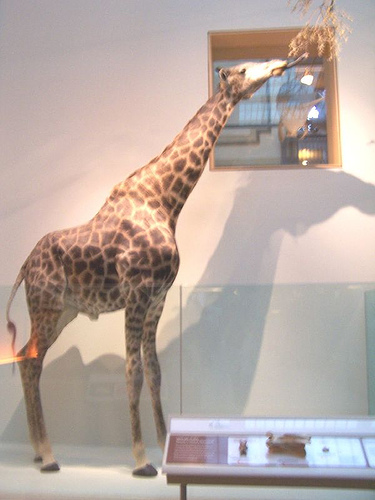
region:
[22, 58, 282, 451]
giraffe is eating leaves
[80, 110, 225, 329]
brown and orange spots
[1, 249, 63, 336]
giraffe has thin tail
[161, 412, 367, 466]
information on stand in front of giraffe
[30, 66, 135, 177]
white wall behind giraffe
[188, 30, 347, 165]
small window near giraffe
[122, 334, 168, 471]
giraffe has light brown legs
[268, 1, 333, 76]
small branch near window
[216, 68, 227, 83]
giraffe has small horns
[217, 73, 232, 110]
giraffe has dark ears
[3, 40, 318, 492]
Tall brown and tan giraffe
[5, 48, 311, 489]
This is not a real giraffe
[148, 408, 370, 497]
Small information sign infront of display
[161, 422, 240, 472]
White lettering on brown information sign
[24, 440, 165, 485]
Black hooves of giraffe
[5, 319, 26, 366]
Small piece of brown hair on giraffe tail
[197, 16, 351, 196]
Small brown window on white wall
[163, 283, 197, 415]
Black line going down wall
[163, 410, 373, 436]
White heading on information board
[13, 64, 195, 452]
Brown spots on giraffe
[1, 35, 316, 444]
the display of the giraffe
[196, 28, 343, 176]
the window in the wall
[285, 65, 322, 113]
the reflection on the window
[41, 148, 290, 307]
the giraffe is spotted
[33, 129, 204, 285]
the spots are brown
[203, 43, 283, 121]
the head of the giraffe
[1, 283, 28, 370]
the tail of the giraffe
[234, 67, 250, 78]
the eye of the giraffe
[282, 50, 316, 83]
the tongue of the giraffe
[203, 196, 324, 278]
the shadow on the wall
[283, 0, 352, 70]
tree branch with leaves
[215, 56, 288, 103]
giraffe's head positioned to eat leaves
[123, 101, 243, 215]
long neck of the giraffe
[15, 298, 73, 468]
hind legs of the giraffe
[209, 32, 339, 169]
monitoring window behind the giraffe and the leaves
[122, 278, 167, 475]
front legs of the giraffe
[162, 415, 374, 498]
podium with basic information on giraffes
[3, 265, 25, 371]
tail of the giraffe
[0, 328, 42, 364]
orange and yellow lens flare on the lower left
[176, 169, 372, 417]
shadow cast by the lighting on the giraffe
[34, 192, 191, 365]
This is a giraffe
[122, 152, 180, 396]
The giraffe is tall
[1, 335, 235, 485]
These are four legs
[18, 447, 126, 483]
These are four hooves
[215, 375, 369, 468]
This is a small sign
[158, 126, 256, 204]
This is a long neck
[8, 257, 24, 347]
This is a tail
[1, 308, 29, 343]
The tail is medium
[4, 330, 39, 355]
This is long fur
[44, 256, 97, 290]
The animal is spotted